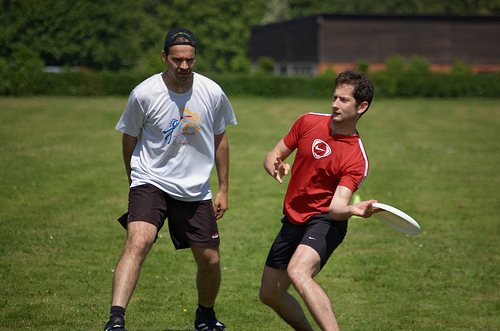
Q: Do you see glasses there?
A: No, there are no glasses.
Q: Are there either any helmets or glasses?
A: No, there are no glasses or helmets.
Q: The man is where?
A: The man is in the grass.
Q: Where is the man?
A: The man is in the grass.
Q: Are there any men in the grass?
A: Yes, there is a man in the grass.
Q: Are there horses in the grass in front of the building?
A: No, there is a man in the grass.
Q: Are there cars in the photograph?
A: No, there are no cars.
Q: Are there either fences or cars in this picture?
A: No, there are no cars or fences.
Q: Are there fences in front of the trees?
A: No, there is a person in front of the trees.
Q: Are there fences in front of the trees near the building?
A: No, there is a person in front of the trees.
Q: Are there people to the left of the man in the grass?
A: Yes, there is a person to the left of the man.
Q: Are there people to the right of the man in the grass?
A: No, the person is to the left of the man.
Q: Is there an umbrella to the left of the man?
A: No, there is a person to the left of the man.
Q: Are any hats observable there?
A: Yes, there is a hat.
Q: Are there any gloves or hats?
A: Yes, there is a hat.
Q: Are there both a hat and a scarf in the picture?
A: No, there is a hat but no scarves.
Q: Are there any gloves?
A: No, there are no gloves.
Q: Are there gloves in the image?
A: No, there are no gloves.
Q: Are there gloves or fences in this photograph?
A: No, there are no gloves or fences.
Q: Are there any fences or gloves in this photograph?
A: No, there are no gloves or fences.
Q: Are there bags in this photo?
A: No, there are no bags.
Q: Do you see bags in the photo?
A: No, there are no bags.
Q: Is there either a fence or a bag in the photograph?
A: No, there are no bags or fences.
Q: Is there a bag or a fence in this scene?
A: No, there are no bags or fences.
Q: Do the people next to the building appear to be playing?
A: Yes, the people are playing.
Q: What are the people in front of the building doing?
A: The people are playing.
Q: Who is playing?
A: The people are playing.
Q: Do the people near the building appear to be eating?
A: No, the people are playing.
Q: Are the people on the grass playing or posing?
A: The people are playing.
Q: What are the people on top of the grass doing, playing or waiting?
A: The people are playing.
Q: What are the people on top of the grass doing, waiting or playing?
A: The people are playing.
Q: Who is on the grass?
A: The people are on the grass.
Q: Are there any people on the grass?
A: Yes, there are people on the grass.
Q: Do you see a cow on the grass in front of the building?
A: No, there are people on the grass.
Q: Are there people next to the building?
A: Yes, there are people next to the building.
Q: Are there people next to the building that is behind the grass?
A: Yes, there are people next to the building.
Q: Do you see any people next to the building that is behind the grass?
A: Yes, there are people next to the building.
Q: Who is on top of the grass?
A: The people are on top of the grass.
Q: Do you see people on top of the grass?
A: Yes, there are people on top of the grass.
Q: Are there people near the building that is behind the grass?
A: Yes, there are people near the building.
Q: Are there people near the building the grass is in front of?
A: Yes, there are people near the building.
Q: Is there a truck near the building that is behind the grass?
A: No, there are people near the building.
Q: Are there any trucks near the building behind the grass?
A: No, there are people near the building.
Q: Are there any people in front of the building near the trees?
A: Yes, there are people in front of the building.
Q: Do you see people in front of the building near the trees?
A: Yes, there are people in front of the building.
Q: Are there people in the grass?
A: Yes, there are people in the grass.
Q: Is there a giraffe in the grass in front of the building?
A: No, there are people in the grass.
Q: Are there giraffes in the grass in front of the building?
A: No, there are people in the grass.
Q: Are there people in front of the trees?
A: Yes, there are people in front of the trees.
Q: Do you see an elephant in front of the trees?
A: No, there are people in front of the trees.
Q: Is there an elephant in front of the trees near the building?
A: No, there are people in front of the trees.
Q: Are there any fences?
A: No, there are no fences.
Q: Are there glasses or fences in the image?
A: No, there are no fences or glasses.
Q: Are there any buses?
A: No, there are no buses.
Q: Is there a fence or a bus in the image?
A: No, there are no buses or fences.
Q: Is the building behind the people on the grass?
A: Yes, the building is behind the people.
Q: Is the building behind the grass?
A: Yes, the building is behind the grass.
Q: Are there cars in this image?
A: No, there are no cars.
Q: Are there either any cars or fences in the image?
A: No, there are no cars or fences.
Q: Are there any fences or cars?
A: No, there are no cars or fences.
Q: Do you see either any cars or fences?
A: No, there are no cars or fences.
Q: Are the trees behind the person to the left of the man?
A: Yes, the trees are behind the person.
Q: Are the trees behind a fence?
A: No, the trees are behind the person.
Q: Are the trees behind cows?
A: No, the trees are behind the people.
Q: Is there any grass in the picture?
A: Yes, there is grass.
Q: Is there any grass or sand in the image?
A: Yes, there is grass.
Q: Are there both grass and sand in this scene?
A: No, there is grass but no sand.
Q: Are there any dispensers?
A: No, there are no dispensers.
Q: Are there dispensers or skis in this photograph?
A: No, there are no dispensers or skis.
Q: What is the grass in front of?
A: The grass is in front of the building.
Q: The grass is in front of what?
A: The grass is in front of the building.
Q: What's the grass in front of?
A: The grass is in front of the building.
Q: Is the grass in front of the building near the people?
A: Yes, the grass is in front of the building.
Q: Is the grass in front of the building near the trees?
A: Yes, the grass is in front of the building.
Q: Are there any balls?
A: No, there are no balls.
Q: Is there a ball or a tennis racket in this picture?
A: No, there are no balls or rackets.